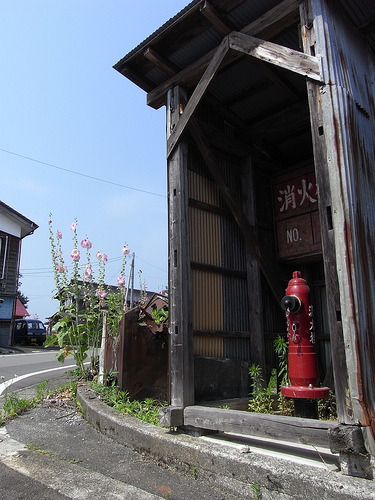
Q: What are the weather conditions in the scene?
A: It is clear.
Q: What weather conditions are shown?
A: It is clear.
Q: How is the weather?
A: It is clear.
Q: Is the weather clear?
A: Yes, it is clear.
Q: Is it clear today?
A: Yes, it is clear.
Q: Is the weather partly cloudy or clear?
A: It is clear.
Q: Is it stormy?
A: No, it is clear.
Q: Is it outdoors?
A: Yes, it is outdoors.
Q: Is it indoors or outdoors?
A: It is outdoors.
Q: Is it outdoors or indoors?
A: It is outdoors.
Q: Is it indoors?
A: No, it is outdoors.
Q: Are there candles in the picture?
A: No, there are no candles.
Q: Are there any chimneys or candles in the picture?
A: No, there are no candles or chimneys.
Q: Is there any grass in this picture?
A: Yes, there is grass.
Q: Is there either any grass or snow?
A: Yes, there is grass.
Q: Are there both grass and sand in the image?
A: No, there is grass but no sand.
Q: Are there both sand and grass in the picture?
A: No, there is grass but no sand.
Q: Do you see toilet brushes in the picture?
A: No, there are no toilet brushes.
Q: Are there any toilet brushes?
A: No, there are no toilet brushes.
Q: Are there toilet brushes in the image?
A: No, there are no toilet brushes.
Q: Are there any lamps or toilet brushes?
A: No, there are no toilet brushes or lamps.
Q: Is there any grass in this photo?
A: Yes, there is grass.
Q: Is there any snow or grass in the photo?
A: Yes, there is grass.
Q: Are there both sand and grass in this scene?
A: No, there is grass but no sand.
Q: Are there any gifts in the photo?
A: No, there are no gifts.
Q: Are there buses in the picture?
A: No, there are no buses.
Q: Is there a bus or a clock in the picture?
A: No, there are no buses or clocks.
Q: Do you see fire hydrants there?
A: Yes, there is a fire hydrant.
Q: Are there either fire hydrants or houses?
A: Yes, there is a fire hydrant.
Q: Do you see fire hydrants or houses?
A: Yes, there is a fire hydrant.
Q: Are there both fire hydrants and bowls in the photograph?
A: No, there is a fire hydrant but no bowls.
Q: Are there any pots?
A: No, there are no pots.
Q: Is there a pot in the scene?
A: No, there are no pots.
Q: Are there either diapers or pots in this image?
A: No, there are no pots or diapers.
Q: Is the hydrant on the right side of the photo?
A: Yes, the hydrant is on the right of the image.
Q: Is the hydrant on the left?
A: No, the hydrant is on the right of the image.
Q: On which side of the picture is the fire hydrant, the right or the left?
A: The fire hydrant is on the right of the image.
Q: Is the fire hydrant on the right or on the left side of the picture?
A: The fire hydrant is on the right of the image.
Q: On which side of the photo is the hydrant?
A: The hydrant is on the right of the image.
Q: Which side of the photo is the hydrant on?
A: The hydrant is on the right of the image.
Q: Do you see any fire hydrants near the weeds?
A: Yes, there is a fire hydrant near the weeds.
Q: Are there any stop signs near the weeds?
A: No, there is a fire hydrant near the weeds.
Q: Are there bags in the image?
A: No, there are no bags.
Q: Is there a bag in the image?
A: No, there are no bags.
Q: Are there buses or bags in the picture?
A: No, there are no bags or buses.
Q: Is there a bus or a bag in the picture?
A: No, there are no bags or buses.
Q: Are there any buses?
A: No, there are no buses.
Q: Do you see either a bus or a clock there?
A: No, there are no buses or clocks.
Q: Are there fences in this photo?
A: Yes, there is a fence.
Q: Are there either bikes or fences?
A: Yes, there is a fence.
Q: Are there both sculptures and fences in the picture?
A: No, there is a fence but no sculptures.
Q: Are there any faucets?
A: No, there are no faucets.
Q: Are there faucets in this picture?
A: No, there are no faucets.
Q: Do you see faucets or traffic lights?
A: No, there are no faucets or traffic lights.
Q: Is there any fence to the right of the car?
A: Yes, there is a fence to the right of the car.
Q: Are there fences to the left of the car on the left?
A: No, the fence is to the right of the car.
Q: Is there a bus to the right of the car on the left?
A: No, there is a fence to the right of the car.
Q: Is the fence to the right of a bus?
A: No, the fence is to the right of the car.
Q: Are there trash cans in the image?
A: No, there are no trash cans.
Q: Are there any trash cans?
A: No, there are no trash cans.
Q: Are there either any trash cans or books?
A: No, there are no trash cans or books.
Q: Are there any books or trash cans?
A: No, there are no trash cans or books.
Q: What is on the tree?
A: The flowers are on the tree.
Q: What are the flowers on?
A: The flowers are on the tree.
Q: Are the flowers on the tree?
A: Yes, the flowers are on the tree.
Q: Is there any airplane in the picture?
A: No, there are no airplanes.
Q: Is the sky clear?
A: Yes, the sky is clear.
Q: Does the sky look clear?
A: Yes, the sky is clear.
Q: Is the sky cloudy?
A: No, the sky is clear.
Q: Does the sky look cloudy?
A: No, the sky is clear.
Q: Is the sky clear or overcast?
A: The sky is clear.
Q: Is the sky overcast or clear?
A: The sky is clear.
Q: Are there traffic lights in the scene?
A: No, there are no traffic lights.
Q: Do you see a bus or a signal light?
A: No, there are no traffic lights or buses.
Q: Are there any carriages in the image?
A: No, there are no carriages.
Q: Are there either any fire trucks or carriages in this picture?
A: No, there are no carriages or fire trucks.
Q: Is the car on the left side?
A: Yes, the car is on the left of the image.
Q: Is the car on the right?
A: No, the car is on the left of the image.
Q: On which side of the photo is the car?
A: The car is on the left of the image.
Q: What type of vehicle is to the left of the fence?
A: The vehicle is a car.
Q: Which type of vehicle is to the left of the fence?
A: The vehicle is a car.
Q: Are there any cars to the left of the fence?
A: Yes, there is a car to the left of the fence.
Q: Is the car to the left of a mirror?
A: No, the car is to the left of the fence.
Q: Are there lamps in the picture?
A: No, there are no lamps.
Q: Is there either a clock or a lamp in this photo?
A: No, there are no lamps or clocks.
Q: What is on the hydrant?
A: The chain is on the hydrant.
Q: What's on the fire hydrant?
A: The chain is on the hydrant.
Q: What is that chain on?
A: The chain is on the hydrant.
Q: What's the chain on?
A: The chain is on the hydrant.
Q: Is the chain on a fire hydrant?
A: Yes, the chain is on a fire hydrant.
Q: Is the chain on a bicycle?
A: No, the chain is on a fire hydrant.